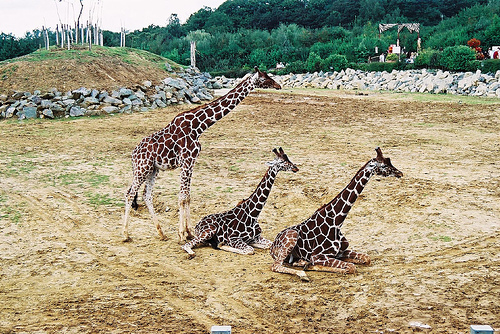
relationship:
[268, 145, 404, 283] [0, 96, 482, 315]
animal sitting in dirt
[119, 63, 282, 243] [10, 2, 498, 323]
animal standing in nature park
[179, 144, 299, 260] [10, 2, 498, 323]
animal lying in nature park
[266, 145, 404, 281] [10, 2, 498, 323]
animal lying in nature park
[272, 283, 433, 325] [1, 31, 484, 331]
dirt lying in pen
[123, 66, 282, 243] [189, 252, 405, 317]
animal laying on dirt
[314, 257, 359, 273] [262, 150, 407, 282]
leg on giraffe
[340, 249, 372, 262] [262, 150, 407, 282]
leg on giraffe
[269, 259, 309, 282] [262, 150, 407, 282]
leg on giraffe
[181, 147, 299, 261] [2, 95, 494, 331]
animal laying on ground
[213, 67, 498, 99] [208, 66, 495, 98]
wall made of stone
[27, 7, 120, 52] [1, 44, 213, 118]
trees on mound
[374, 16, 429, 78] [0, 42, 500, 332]
structure at side of area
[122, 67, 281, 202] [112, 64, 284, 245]
spots on giraffe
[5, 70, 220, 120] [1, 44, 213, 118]
rocks around mound